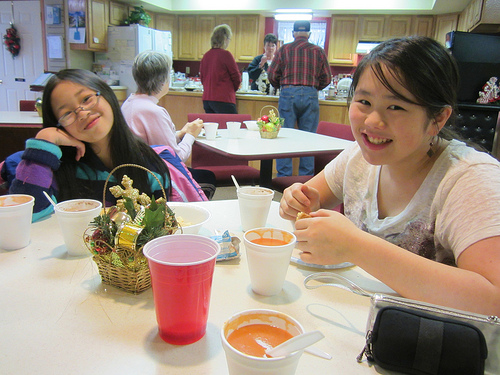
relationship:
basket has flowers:
[92, 163, 178, 292] [88, 230, 110, 253]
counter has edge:
[188, 114, 358, 161] [194, 140, 343, 159]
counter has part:
[188, 114, 358, 161] [293, 138, 306, 147]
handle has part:
[0, 80, 2, 85] [1, 80, 3, 82]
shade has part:
[276, 22, 325, 49] [283, 28, 287, 33]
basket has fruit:
[258, 104, 282, 139] [261, 116, 269, 122]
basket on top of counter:
[258, 104, 282, 139] [188, 114, 358, 161]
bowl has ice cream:
[164, 206, 209, 234] [174, 215, 189, 225]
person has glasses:
[8, 70, 170, 223] [54, 90, 101, 126]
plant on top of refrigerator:
[125, 4, 150, 26] [93, 25, 172, 95]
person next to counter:
[268, 24, 331, 178] [154, 90, 351, 182]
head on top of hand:
[50, 78, 115, 142] [36, 127, 86, 159]